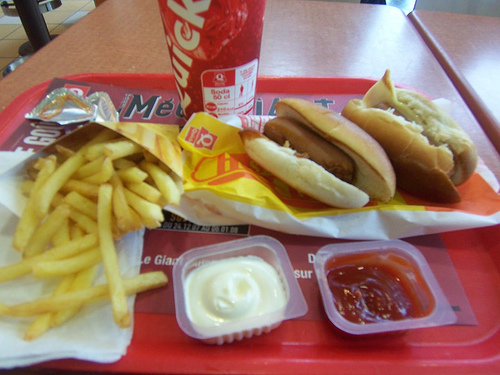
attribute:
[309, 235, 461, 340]
container — small, plastic, clear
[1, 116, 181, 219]
bag — small, yellow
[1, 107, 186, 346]
french fries — yellow, golden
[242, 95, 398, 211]
bun — brown, white, toasted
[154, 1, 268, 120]
cup — red, white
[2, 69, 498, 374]
tray — red, plastic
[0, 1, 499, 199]
table — brown, wood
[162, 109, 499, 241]
bag — yellow, orange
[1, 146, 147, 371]
napkins — white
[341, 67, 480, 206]
bun — brown, white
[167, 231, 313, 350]
packet — small, plastic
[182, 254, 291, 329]
mayonnaise — white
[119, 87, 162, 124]
letter — m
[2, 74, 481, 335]
liner — paper, red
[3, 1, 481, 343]
lunch — fast food